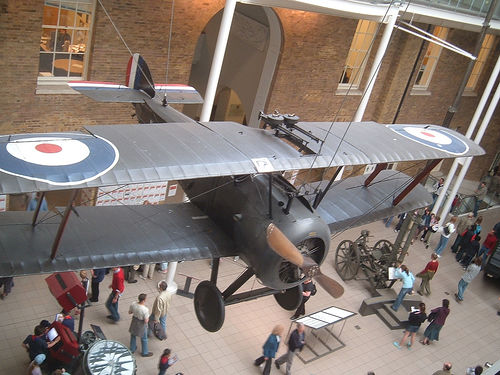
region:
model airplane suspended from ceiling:
[5, 53, 479, 335]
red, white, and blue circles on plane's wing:
[7, 116, 479, 192]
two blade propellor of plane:
[257, 228, 362, 308]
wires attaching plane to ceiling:
[125, 52, 498, 195]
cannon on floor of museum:
[333, 223, 416, 294]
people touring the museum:
[5, 193, 487, 373]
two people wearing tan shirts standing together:
[131, 280, 173, 350]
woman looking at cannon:
[384, 262, 408, 307]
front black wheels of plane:
[175, 268, 310, 320]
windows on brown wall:
[38, 45, 491, 102]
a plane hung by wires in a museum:
[1, 7, 481, 335]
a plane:
[7, 55, 489, 318]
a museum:
[5, 1, 497, 373]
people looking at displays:
[40, 172, 495, 372]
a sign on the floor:
[292, 295, 358, 365]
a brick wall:
[10, 0, 497, 254]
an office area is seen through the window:
[42, 1, 89, 95]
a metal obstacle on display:
[340, 229, 425, 336]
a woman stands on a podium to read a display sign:
[385, 260, 417, 320]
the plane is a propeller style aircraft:
[2, 51, 462, 336]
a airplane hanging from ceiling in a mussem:
[0, 122, 483, 351]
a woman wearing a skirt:
[425, 304, 456, 361]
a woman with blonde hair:
[273, 322, 290, 341]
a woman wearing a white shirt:
[443, 214, 459, 244]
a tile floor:
[350, 324, 397, 361]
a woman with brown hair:
[393, 258, 412, 281]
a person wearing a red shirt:
[422, 240, 444, 277]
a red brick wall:
[286, 25, 346, 122]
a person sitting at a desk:
[41, 22, 79, 66]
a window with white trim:
[28, 0, 95, 94]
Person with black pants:
[248, 320, 280, 373]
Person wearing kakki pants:
[283, 319, 310, 374]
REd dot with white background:
[33, 135, 62, 155]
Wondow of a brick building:
[23, 3, 111, 108]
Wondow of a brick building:
[343, 13, 370, 118]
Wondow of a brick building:
[409, 23, 445, 119]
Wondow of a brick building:
[467, 26, 499, 126]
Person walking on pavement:
[107, 268, 129, 333]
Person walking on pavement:
[377, 255, 417, 309]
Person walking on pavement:
[405, 247, 447, 292]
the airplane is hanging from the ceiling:
[1, 51, 488, 333]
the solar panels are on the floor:
[284, 305, 357, 364]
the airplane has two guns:
[256, 108, 323, 148]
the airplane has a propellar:
[264, 221, 346, 298]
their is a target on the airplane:
[1, 130, 120, 185]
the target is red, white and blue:
[1, 130, 120, 187]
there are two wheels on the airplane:
[193, 280, 304, 333]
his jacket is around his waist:
[127, 293, 152, 358]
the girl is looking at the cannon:
[334, 228, 424, 330]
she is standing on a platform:
[358, 263, 425, 328]